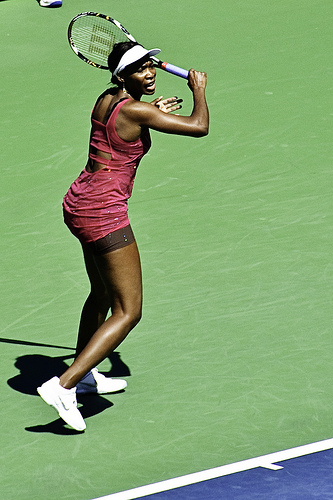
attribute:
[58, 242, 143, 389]
leg — strong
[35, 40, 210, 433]
player — tennis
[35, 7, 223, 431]
women — playing tennis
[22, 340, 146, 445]
shoes — tennis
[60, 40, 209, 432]
woman — playing tennis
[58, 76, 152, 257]
outfit — sleeveless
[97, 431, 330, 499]
marking — white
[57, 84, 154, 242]
top — tank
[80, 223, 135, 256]
bottom — brown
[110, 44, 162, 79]
visor — head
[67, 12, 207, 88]
tennis racket — multicolored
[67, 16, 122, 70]
net — white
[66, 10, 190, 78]
racket — tennis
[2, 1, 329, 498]
tennis court — green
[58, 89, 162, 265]
outfit — red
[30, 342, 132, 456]
shoe — white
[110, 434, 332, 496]
ground — blue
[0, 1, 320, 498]
court — tennis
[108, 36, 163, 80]
visor — white